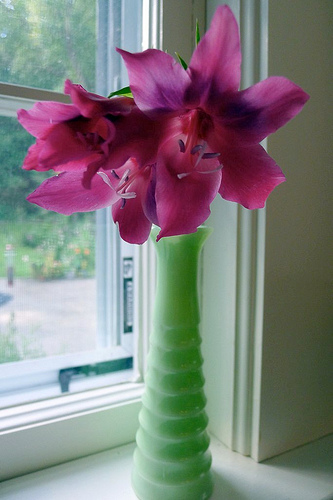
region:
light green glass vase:
[127, 224, 228, 497]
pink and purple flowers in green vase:
[42, 14, 306, 248]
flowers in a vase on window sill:
[17, 22, 300, 494]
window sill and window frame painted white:
[28, 357, 254, 497]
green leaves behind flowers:
[114, 25, 208, 103]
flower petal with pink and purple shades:
[223, 62, 311, 142]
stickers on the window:
[42, 254, 142, 399]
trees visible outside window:
[15, 13, 86, 263]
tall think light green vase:
[126, 224, 229, 495]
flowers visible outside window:
[25, 224, 93, 280]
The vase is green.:
[132, 223, 211, 498]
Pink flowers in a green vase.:
[15, 3, 309, 498]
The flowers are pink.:
[16, 3, 309, 244]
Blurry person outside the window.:
[4, 243, 14, 285]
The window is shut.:
[0, 1, 205, 481]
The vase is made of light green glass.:
[131, 227, 213, 499]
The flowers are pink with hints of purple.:
[16, 3, 310, 243]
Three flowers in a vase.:
[17, 3, 310, 498]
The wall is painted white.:
[258, 0, 332, 463]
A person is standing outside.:
[4, 244, 15, 285]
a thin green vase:
[125, 226, 232, 498]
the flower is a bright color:
[14, 3, 330, 285]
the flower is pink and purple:
[3, 0, 324, 269]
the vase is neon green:
[122, 219, 254, 499]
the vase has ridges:
[121, 222, 259, 496]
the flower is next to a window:
[10, 4, 319, 498]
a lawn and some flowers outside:
[1, 219, 99, 278]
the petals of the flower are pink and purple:
[11, 2, 313, 265]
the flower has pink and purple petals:
[5, 0, 331, 263]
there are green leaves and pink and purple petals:
[8, 0, 329, 261]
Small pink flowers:
[22, 1, 297, 257]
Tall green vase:
[107, 214, 238, 498]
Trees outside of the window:
[0, 0, 112, 286]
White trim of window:
[0, 0, 215, 483]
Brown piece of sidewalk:
[1, 268, 113, 368]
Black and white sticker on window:
[112, 252, 160, 346]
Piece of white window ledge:
[0, 427, 331, 499]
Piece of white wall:
[207, 0, 332, 463]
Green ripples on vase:
[113, 316, 236, 499]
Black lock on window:
[31, 349, 149, 410]